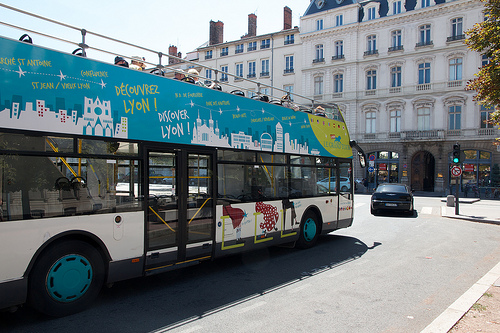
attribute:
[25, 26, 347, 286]
bus — double-decker, white, green, blue, black, yellow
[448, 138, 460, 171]
traffic light — green, black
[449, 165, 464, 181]
sign — white, red, black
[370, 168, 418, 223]
car — parked, dark, gray, black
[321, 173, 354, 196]
car — white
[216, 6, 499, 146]
buildng — white, large, tall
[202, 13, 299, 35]
chimneys — brick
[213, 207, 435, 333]
street — concrete, gray, grey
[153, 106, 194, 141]
print — white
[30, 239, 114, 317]
wheel — black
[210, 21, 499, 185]
building — large, white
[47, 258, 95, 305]
hubcap — blue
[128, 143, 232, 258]
doors — double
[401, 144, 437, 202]
doorway — arched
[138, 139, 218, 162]
frame — black